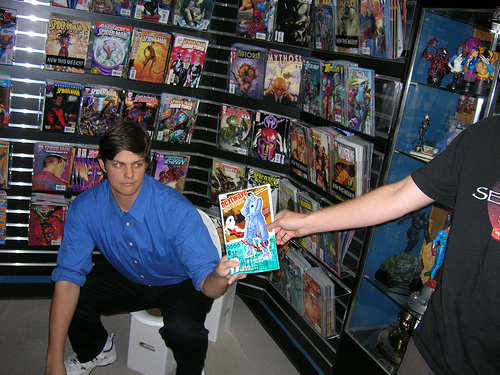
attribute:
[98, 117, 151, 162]
hair — dark, short, brown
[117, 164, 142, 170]
eyes — open, red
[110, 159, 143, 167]
eyebrows — brown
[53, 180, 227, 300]
shirt — black, blue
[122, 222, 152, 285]
buttons — white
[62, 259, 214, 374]
pants — black, dark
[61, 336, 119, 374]
sneakers — white, shoe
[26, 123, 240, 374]
man — person, sitting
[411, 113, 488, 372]
part — black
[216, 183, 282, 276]
comic book — asian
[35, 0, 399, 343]
magazines — comic books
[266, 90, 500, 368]
man — reaching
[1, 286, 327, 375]
floor — light